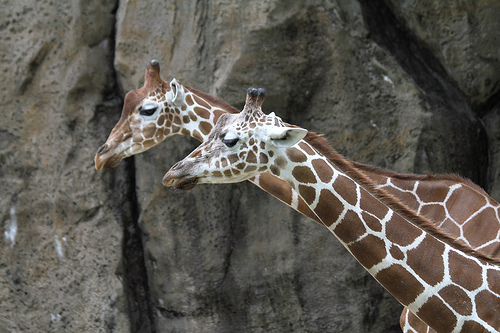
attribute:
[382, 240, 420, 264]
spot — one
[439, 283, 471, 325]
spot — brown